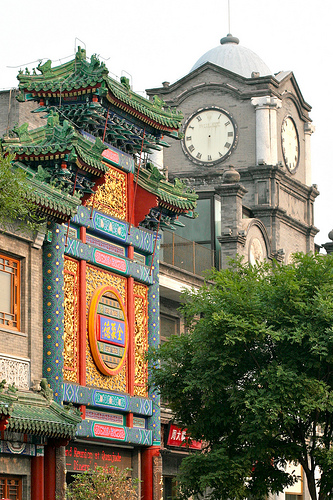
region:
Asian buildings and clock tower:
[16, 46, 325, 336]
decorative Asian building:
[9, 59, 198, 336]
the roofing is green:
[22, 55, 203, 231]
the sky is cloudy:
[14, 0, 331, 198]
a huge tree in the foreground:
[109, 235, 329, 444]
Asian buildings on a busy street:
[33, 258, 239, 498]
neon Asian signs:
[51, 405, 176, 493]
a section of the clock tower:
[167, 168, 257, 348]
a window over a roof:
[1, 229, 79, 440]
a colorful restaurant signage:
[67, 258, 150, 396]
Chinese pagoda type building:
[8, 81, 186, 478]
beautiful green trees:
[164, 239, 323, 485]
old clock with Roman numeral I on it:
[166, 101, 243, 180]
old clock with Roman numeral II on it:
[163, 98, 241, 178]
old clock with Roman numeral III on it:
[165, 99, 253, 174]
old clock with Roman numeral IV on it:
[159, 100, 257, 178]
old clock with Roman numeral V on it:
[141, 94, 238, 172]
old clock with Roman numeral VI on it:
[159, 102, 244, 173]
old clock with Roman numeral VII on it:
[176, 102, 243, 185]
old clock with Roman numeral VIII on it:
[150, 94, 250, 177]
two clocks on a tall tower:
[141, 0, 317, 274]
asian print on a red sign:
[165, 422, 204, 449]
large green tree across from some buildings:
[136, 248, 332, 497]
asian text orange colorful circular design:
[83, 281, 137, 378]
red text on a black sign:
[64, 446, 138, 471]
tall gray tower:
[143, 1, 320, 269]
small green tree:
[63, 462, 142, 498]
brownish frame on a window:
[0, 251, 29, 330]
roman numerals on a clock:
[177, 103, 248, 166]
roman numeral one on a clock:
[213, 112, 224, 118]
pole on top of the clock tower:
[212, 0, 254, 53]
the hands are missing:
[181, 105, 246, 169]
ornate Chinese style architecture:
[14, 38, 193, 157]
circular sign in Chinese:
[87, 286, 131, 379]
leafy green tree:
[150, 225, 328, 492]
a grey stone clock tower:
[150, 10, 322, 290]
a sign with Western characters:
[59, 440, 138, 475]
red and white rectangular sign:
[164, 417, 225, 464]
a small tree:
[48, 468, 148, 499]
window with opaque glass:
[2, 252, 31, 338]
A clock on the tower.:
[179, 100, 245, 168]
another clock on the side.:
[279, 113, 303, 179]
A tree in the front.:
[182, 252, 332, 498]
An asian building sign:
[85, 277, 133, 380]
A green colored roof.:
[21, 53, 184, 142]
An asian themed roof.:
[3, 383, 86, 442]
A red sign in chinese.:
[165, 422, 211, 455]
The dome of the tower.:
[185, 26, 279, 80]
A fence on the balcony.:
[159, 226, 219, 288]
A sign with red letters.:
[68, 445, 127, 477]